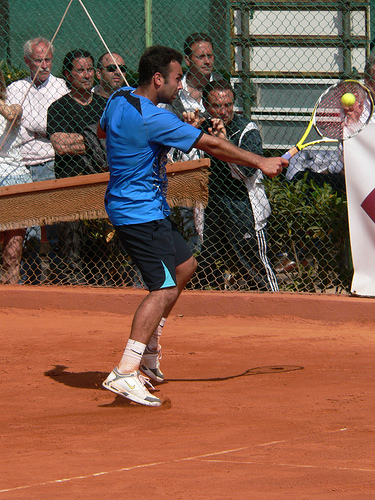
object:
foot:
[100, 363, 164, 407]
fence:
[2, 0, 375, 301]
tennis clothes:
[98, 87, 204, 290]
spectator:
[47, 48, 112, 177]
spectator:
[92, 50, 129, 110]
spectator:
[180, 31, 220, 128]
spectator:
[180, 79, 279, 291]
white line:
[2, 423, 375, 493]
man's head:
[137, 44, 185, 106]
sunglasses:
[106, 63, 128, 75]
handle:
[264, 142, 297, 180]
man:
[7, 35, 72, 186]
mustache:
[38, 67, 49, 75]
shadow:
[43, 354, 307, 407]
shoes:
[102, 363, 164, 409]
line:
[195, 455, 375, 481]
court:
[0, 283, 375, 499]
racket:
[281, 77, 375, 165]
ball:
[340, 92, 356, 112]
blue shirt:
[99, 84, 203, 228]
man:
[96, 42, 291, 409]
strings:
[326, 94, 352, 130]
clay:
[0, 281, 375, 498]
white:
[135, 387, 144, 404]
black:
[140, 255, 154, 270]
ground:
[0, 281, 375, 499]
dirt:
[58, 454, 107, 499]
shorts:
[111, 207, 192, 293]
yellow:
[295, 131, 309, 155]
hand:
[258, 154, 294, 181]